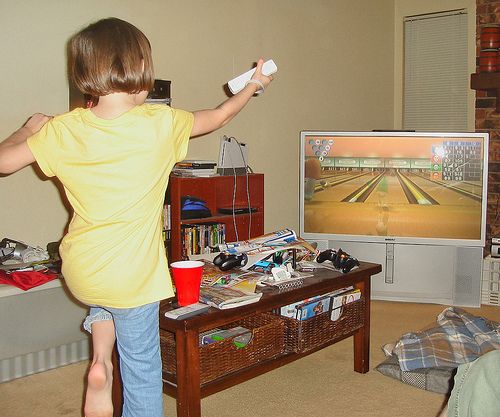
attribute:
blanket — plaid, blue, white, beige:
[382, 303, 499, 389]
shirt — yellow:
[25, 102, 195, 308]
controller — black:
[315, 245, 358, 277]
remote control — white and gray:
[162, 295, 212, 317]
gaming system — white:
[215, 130, 249, 174]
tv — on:
[295, 127, 475, 292]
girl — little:
[2, 16, 275, 416]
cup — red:
[162, 231, 224, 316]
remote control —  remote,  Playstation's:
[213, 250, 242, 270]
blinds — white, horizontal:
[406, 20, 466, 125]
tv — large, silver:
[289, 122, 494, 311]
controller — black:
[315, 247, 360, 272]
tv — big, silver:
[287, 126, 487, 260]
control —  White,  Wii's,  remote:
[228, 59, 278, 94]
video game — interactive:
[302, 135, 485, 242]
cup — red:
[166, 252, 208, 304]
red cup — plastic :
[168, 259, 205, 307]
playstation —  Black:
[315, 248, 358, 273]